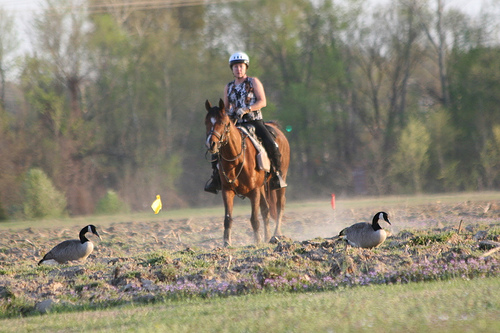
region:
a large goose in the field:
[337, 206, 394, 254]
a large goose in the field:
[37, 218, 104, 273]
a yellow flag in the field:
[149, 192, 171, 239]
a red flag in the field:
[323, 186, 342, 229]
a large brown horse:
[193, 98, 288, 242]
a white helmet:
[225, 50, 249, 67]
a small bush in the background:
[15, 171, 68, 218]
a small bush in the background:
[93, 187, 126, 213]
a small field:
[3, 194, 499, 309]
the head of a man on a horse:
[226, 47, 256, 78]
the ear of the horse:
[200, 90, 217, 111]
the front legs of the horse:
[221, 188, 261, 243]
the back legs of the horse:
[261, 187, 294, 239]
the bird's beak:
[385, 215, 395, 229]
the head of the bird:
[378, 200, 393, 223]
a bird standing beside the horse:
[331, 206, 401, 254]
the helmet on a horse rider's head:
[224, 43, 259, 65]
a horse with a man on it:
[198, 102, 303, 245]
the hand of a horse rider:
[238, 76, 279, 113]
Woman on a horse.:
[177, 21, 349, 278]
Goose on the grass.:
[294, 137, 453, 301]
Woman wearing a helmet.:
[179, 29, 344, 239]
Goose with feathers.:
[335, 214, 380, 250]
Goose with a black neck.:
[21, 169, 138, 313]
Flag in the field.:
[127, 182, 202, 241]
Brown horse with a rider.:
[175, 33, 344, 315]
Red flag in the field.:
[288, 144, 392, 237]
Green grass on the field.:
[156, 203, 423, 331]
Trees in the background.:
[29, 34, 242, 237]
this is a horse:
[135, 52, 331, 200]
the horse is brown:
[185, 120, 365, 326]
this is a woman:
[213, 86, 258, 100]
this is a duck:
[22, 248, 150, 249]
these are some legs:
[166, 164, 288, 240]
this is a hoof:
[221, 232, 293, 262]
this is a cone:
[315, 193, 360, 209]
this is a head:
[181, 100, 256, 156]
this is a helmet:
[180, 13, 300, 80]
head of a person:
[227, 49, 249, 83]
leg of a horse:
[201, 199, 241, 267]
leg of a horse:
[244, 201, 265, 248]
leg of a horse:
[272, 196, 286, 227]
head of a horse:
[197, 93, 232, 158]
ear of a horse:
[200, 89, 220, 113]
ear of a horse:
[214, 93, 235, 123]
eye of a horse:
[200, 116, 234, 133]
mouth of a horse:
[207, 138, 229, 162]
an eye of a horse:
[212, 121, 226, 135]